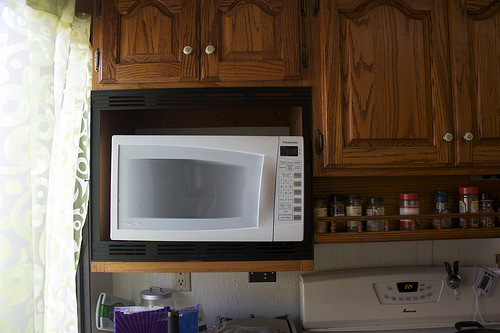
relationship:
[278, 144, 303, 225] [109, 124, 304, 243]
display on oven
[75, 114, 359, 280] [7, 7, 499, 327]
microwave in kitchen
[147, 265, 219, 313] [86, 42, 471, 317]
electrical outlet on wall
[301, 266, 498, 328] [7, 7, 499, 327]
oven in kitchen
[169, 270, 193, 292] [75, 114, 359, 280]
electrical plug underneath microwave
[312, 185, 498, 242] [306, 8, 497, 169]
spice rack underneath cabinet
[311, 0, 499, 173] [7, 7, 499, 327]
cabinet in kitchen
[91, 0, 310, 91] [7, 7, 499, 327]
cabinet in kitchen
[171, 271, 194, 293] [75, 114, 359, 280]
outlet near microwave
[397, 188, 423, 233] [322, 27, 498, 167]
jar below cabinet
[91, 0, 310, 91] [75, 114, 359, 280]
cabinet above microwave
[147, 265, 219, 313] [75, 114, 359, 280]
electrical outlet under microwave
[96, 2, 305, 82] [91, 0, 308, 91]
brown doors on cabinets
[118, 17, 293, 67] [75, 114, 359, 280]
cabinets above microwave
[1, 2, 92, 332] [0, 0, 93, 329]
curtains on window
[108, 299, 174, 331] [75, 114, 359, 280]
purple bag under microwave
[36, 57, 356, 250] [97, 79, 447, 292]
microwave over counter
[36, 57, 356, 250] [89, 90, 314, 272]
microwave in stand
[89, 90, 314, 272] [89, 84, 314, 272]
stand built into cabinet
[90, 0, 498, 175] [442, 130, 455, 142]
cabinets with knob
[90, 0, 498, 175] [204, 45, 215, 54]
cabinets with knob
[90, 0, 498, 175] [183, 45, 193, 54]
cabinets with knob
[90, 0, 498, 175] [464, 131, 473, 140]
cabinets with knob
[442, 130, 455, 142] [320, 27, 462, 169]
knob on cabinet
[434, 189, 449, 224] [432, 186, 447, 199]
bottle with green cap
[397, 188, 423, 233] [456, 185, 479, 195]
jar with red cap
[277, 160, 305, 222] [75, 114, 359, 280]
controls for microwave